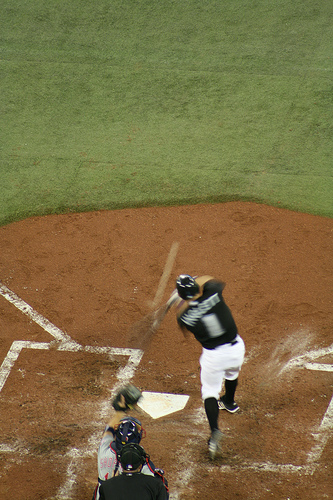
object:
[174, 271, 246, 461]
man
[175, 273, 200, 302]
helmet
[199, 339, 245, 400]
pants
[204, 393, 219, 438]
sock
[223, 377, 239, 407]
sock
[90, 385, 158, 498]
man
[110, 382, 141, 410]
mitt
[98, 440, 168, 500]
vest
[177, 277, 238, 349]
shirt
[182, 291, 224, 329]
lettering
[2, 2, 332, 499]
field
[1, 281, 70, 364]
line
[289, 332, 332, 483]
line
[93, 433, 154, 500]
shirt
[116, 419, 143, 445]
helmet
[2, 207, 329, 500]
dirt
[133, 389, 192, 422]
home base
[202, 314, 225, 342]
1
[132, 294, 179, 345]
bat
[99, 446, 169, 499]
umpire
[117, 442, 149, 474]
head protection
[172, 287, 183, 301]
hand